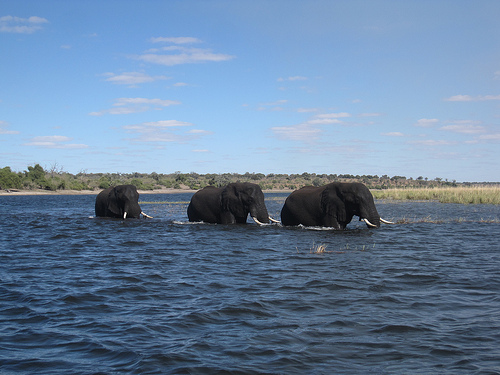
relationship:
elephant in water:
[281, 183, 391, 229] [6, 196, 500, 374]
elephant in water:
[187, 182, 270, 225] [6, 196, 500, 374]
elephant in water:
[95, 185, 140, 219] [6, 196, 500, 374]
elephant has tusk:
[281, 183, 391, 229] [379, 215, 395, 225]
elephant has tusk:
[281, 183, 391, 229] [362, 218, 378, 227]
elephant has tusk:
[187, 182, 270, 225] [269, 214, 280, 223]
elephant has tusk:
[187, 182, 270, 225] [253, 218, 268, 227]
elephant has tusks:
[95, 185, 140, 219] [123, 211, 151, 220]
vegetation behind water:
[2, 163, 499, 201] [6, 196, 500, 374]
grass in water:
[297, 243, 343, 252] [6, 196, 500, 374]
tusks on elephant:
[123, 211, 151, 220] [95, 185, 140, 219]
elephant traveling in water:
[94, 185, 154, 220] [6, 196, 500, 374]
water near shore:
[6, 196, 500, 374] [16, 185, 499, 200]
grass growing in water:
[297, 243, 343, 252] [6, 196, 500, 374]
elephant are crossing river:
[94, 185, 154, 220] [6, 196, 500, 374]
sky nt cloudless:
[3, 3, 495, 169] [256, 4, 498, 47]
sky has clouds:
[3, 3, 495, 169] [102, 35, 233, 145]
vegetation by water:
[2, 163, 499, 201] [6, 196, 500, 374]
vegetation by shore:
[2, 163, 499, 201] [16, 185, 499, 200]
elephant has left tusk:
[281, 183, 391, 229] [362, 218, 378, 227]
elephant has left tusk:
[187, 182, 270, 225] [253, 218, 268, 227]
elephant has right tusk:
[281, 183, 391, 229] [379, 215, 395, 225]